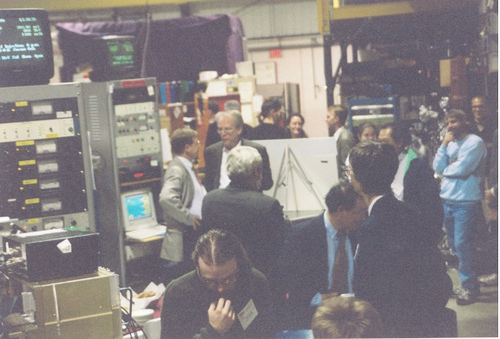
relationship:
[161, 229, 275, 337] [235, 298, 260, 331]
man with tag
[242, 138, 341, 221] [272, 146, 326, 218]
board on stand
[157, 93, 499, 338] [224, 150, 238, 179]
men wearing ties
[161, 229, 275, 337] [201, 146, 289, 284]
man next to man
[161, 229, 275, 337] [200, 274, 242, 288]
man with glasses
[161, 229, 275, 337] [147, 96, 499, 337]
man with people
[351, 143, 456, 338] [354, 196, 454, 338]
jacket on person